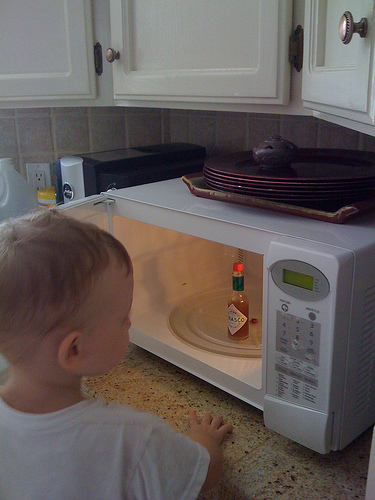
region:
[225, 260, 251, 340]
Small bottle of Tabasco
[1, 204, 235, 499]
Young child looks at a bottle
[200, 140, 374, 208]
Plates stacked on microwave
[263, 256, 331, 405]
Microwave control panel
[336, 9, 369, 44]
Decorative knob on cabinet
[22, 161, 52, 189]
White electrical wall outlet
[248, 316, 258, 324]
Food residue on microwave turn plate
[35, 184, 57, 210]
Yellow and white container in corner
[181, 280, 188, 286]
Food caked inside microwave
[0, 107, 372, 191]
Tiled back-splash in kitchen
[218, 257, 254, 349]
a bottle of Tabasco sauce in the microwave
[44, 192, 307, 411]
a microwave with an open door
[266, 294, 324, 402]
control panel on a microwave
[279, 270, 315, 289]
display on a microwave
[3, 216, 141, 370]
a child with blonde hair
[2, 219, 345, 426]
a child looking at a microwave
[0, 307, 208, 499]
a child wearing a white tee shirt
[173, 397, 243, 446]
a child's hand on a counter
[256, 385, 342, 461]
door release button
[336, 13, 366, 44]
a knob on a cabinet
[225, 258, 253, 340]
a bottle of Tabasco sauce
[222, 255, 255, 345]
the bottle is in the microwave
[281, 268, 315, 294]
the display is blank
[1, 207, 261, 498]
a child is looking in the microwave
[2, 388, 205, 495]
his shirt is white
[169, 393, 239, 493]
his hand is on the counter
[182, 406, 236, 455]
his hand is little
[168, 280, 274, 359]
a turntable in the microwave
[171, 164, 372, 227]
a tray on top of the microwave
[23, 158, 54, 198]
an outlet on the wall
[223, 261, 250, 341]
A bottle of hot sauce.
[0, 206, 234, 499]
A child wearing a white shirt.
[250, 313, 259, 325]
A food crumb in the microwave.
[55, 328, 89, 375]
The ear on a child.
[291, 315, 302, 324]
The number two on a microwave.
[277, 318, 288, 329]
The number four on the microwave.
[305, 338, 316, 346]
The number nine on a microwave.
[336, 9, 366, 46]
The knob on a cabinet door.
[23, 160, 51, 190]
A white wall outlet.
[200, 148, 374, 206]
A stack of plates on top of a microwave.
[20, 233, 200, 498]
this is a boy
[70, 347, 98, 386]
the boy is light skinned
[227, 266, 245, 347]
this is a bottle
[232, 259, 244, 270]
this is the lid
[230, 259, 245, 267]
the lid is red in color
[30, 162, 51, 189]
this is a socket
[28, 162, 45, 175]
the socket is white in color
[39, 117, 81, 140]
this is the wall